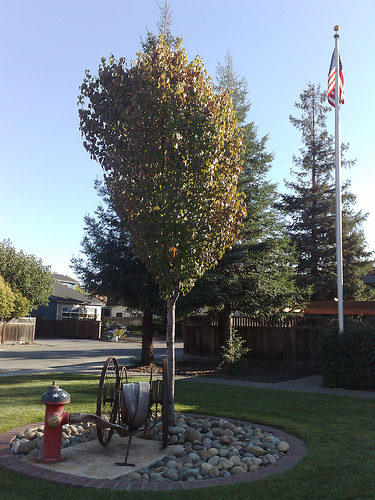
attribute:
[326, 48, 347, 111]
flag — red, blue, white, american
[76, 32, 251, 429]
tree — small, medium, growing, green, tall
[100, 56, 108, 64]
leaf — green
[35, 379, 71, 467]
hydrant — red, yellow, black, tall, blue, white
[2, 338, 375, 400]
pavement — long, concrete, cement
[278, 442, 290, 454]
rock — large, beige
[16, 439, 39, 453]
rock — grey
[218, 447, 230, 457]
rock — white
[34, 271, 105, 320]
house — gray, blue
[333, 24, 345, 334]
post — tall, silver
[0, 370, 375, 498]
grass — green, low, short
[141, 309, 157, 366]
trunk — brown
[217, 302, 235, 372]
trunk — brown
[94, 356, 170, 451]
hose  organizer — dark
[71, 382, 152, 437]
hose — grey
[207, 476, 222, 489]
brick — red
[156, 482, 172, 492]
brick — red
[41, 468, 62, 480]
brick — red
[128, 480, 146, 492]
brick — red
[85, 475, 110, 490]
brick — red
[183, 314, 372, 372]
fence — long, wooden, brown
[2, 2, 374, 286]
sky — blue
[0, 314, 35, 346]
fence — brown, wooden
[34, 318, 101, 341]
fence — brown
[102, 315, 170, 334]
fence — brown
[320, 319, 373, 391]
bush — green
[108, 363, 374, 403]
walkway — grey